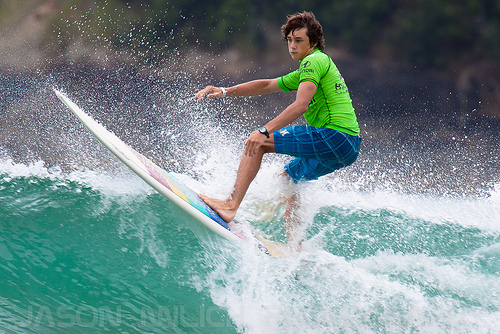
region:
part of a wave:
[407, 228, 434, 262]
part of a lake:
[344, 223, 377, 295]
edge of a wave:
[101, 228, 127, 276]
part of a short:
[290, 125, 297, 140]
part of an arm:
[262, 115, 278, 132]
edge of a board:
[167, 182, 178, 199]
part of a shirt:
[323, 51, 328, 71]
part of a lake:
[163, 276, 174, 285]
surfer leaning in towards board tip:
[173, 5, 375, 271]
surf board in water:
[42, 75, 335, 286]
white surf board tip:
[42, 71, 153, 194]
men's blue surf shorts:
[269, 115, 367, 191]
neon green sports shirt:
[277, 46, 366, 141]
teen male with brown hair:
[187, 8, 367, 253]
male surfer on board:
[182, 5, 371, 264]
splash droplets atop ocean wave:
[5, 2, 498, 219]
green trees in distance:
[5, 0, 497, 109]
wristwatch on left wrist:
[255, 123, 276, 140]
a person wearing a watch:
[254, 122, 274, 137]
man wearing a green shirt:
[281, 65, 356, 127]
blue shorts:
[284, 131, 351, 163]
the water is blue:
[28, 198, 187, 331]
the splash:
[232, 263, 374, 330]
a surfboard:
[66, 103, 153, 161]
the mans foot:
[202, 190, 237, 217]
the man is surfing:
[177, 5, 379, 247]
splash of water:
[376, 142, 469, 191]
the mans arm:
[194, 80, 270, 102]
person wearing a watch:
[189, 0, 375, 260]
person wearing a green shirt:
[165, 4, 371, 264]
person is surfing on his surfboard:
[39, 4, 370, 293]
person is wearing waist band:
[169, 0, 387, 267]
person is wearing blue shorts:
[169, 2, 379, 264]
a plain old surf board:
[41, 84, 300, 274]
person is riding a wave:
[42, 9, 394, 286]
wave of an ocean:
[4, 123, 496, 330]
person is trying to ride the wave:
[40, 8, 382, 283]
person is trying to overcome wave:
[49, 8, 393, 280]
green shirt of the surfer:
[277, 55, 364, 135]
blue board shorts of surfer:
[272, 119, 354, 182]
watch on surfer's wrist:
[256, 124, 268, 135]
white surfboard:
[55, 78, 258, 253]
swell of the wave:
[0, 196, 210, 332]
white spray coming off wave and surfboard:
[15, 13, 487, 188]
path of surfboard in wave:
[178, 215, 493, 332]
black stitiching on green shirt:
[282, 51, 360, 131]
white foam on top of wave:
[6, 151, 499, 225]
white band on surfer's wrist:
[219, 84, 228, 98]